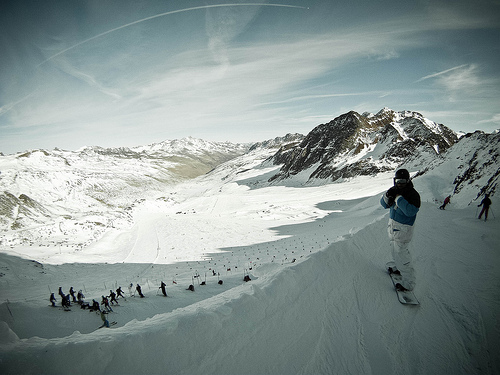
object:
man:
[379, 168, 422, 290]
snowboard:
[386, 260, 420, 306]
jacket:
[381, 184, 420, 233]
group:
[49, 280, 167, 328]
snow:
[1, 174, 500, 374]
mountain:
[0, 135, 255, 230]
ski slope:
[0, 171, 500, 374]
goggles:
[395, 178, 410, 183]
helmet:
[395, 168, 410, 180]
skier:
[159, 281, 167, 297]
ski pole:
[156, 287, 160, 294]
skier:
[136, 283, 145, 298]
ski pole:
[134, 290, 137, 297]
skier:
[476, 194, 495, 222]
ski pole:
[490, 207, 496, 219]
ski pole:
[475, 206, 480, 217]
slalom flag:
[218, 272, 221, 281]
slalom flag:
[205, 272, 207, 281]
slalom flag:
[215, 263, 217, 265]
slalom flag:
[250, 261, 253, 267]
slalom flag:
[285, 257, 288, 260]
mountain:
[269, 107, 460, 183]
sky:
[0, 0, 498, 154]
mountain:
[404, 131, 499, 213]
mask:
[395, 183, 404, 188]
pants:
[389, 220, 415, 291]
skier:
[439, 195, 451, 211]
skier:
[97, 310, 118, 329]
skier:
[48, 293, 58, 308]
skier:
[69, 287, 78, 303]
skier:
[115, 286, 125, 299]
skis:
[99, 321, 117, 329]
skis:
[473, 217, 490, 223]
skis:
[48, 305, 60, 308]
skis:
[136, 295, 149, 298]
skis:
[157, 293, 170, 298]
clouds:
[0, 0, 499, 154]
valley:
[136, 169, 213, 205]